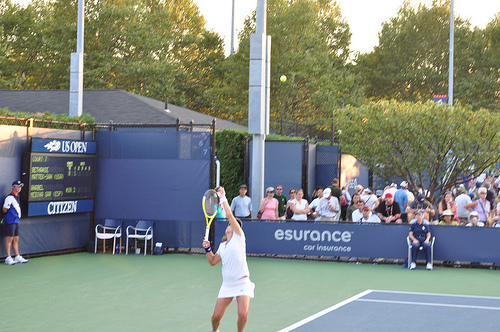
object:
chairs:
[95, 218, 128, 255]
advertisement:
[265, 225, 361, 255]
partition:
[214, 219, 499, 266]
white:
[218, 235, 249, 300]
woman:
[259, 183, 284, 223]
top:
[261, 197, 281, 217]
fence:
[24, 122, 208, 250]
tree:
[332, 100, 499, 216]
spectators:
[238, 186, 489, 223]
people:
[255, 188, 287, 222]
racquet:
[200, 187, 222, 248]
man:
[372, 192, 404, 223]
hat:
[384, 190, 393, 197]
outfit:
[213, 228, 261, 301]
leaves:
[381, 121, 402, 133]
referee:
[404, 208, 436, 271]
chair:
[404, 232, 436, 270]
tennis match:
[4, 244, 496, 331]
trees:
[208, 0, 354, 144]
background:
[3, 4, 499, 122]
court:
[188, 258, 499, 331]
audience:
[381, 171, 417, 222]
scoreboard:
[20, 132, 108, 218]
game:
[377, 296, 469, 330]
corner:
[86, 237, 93, 249]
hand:
[201, 237, 214, 253]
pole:
[209, 115, 221, 186]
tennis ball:
[273, 71, 293, 84]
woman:
[198, 185, 258, 332]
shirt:
[258, 197, 280, 220]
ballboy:
[1, 180, 28, 266]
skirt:
[214, 276, 256, 298]